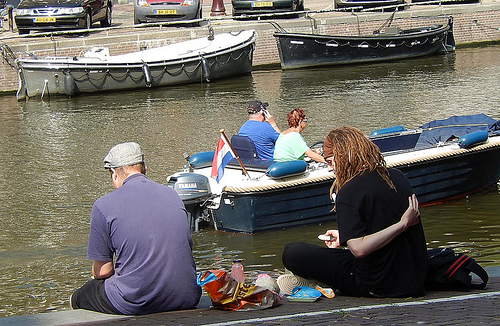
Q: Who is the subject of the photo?
A: The people.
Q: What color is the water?
A: Green.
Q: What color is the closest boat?
A: Blue.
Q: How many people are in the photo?
A: 4.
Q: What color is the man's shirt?
A: Light blue.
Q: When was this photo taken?
A: During the day.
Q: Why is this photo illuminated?
A: Sunlight.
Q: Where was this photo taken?
A: On a canal.